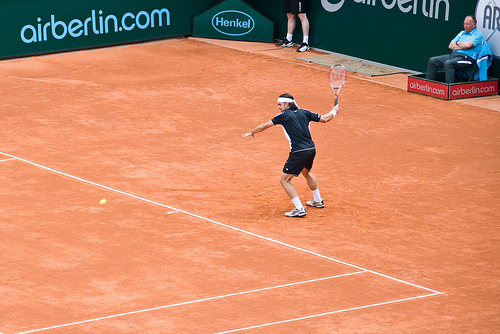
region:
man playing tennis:
[238, 59, 355, 230]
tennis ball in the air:
[97, 192, 109, 205]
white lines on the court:
[0, 149, 445, 331]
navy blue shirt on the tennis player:
[268, 102, 319, 152]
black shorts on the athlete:
[278, 145, 322, 177]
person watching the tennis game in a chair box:
[405, 15, 499, 102]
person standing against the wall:
[277, 0, 310, 54]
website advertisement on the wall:
[16, 0, 190, 53]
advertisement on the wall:
[196, 5, 276, 36]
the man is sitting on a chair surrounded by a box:
[401, 9, 498, 103]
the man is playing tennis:
[227, 44, 404, 225]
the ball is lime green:
[66, 170, 165, 242]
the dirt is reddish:
[115, 64, 260, 231]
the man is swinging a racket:
[212, 34, 389, 262]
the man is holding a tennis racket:
[274, 23, 371, 145]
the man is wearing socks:
[276, 172, 335, 226]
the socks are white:
[270, 181, 331, 213]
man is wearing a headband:
[246, 87, 306, 115]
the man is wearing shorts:
[245, 143, 332, 184]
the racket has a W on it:
[307, 34, 358, 137]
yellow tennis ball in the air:
[96, 195, 108, 205]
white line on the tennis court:
[165, 205, 446, 332]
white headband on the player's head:
[275, 93, 296, 105]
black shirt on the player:
[269, 107, 323, 153]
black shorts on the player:
[280, 145, 317, 176]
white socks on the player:
[290, 186, 323, 210]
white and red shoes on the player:
[281, 196, 325, 218]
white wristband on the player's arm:
[327, 106, 337, 117]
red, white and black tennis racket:
[326, 60, 348, 102]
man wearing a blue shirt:
[450, 28, 486, 60]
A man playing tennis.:
[236, 53, 363, 233]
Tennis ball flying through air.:
[94, 185, 115, 213]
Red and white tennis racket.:
[324, 58, 353, 117]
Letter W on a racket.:
[333, 70, 349, 83]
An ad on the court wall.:
[15, 8, 190, 48]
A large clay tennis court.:
[39, 72, 247, 317]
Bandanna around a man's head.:
[273, 89, 301, 107]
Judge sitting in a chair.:
[424, 7, 486, 90]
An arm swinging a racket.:
[304, 55, 354, 144]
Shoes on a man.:
[275, 170, 342, 225]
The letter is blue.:
[13, 21, 38, 44]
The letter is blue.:
[49, 13, 69, 39]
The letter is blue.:
[41, 22, 52, 44]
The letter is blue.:
[68, 11, 84, 40]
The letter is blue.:
[81, 13, 93, 38]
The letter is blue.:
[89, 3, 100, 36]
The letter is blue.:
[102, 9, 119, 36]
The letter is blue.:
[120, 8, 136, 34]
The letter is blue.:
[133, 6, 151, 32]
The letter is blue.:
[146, 4, 173, 31]